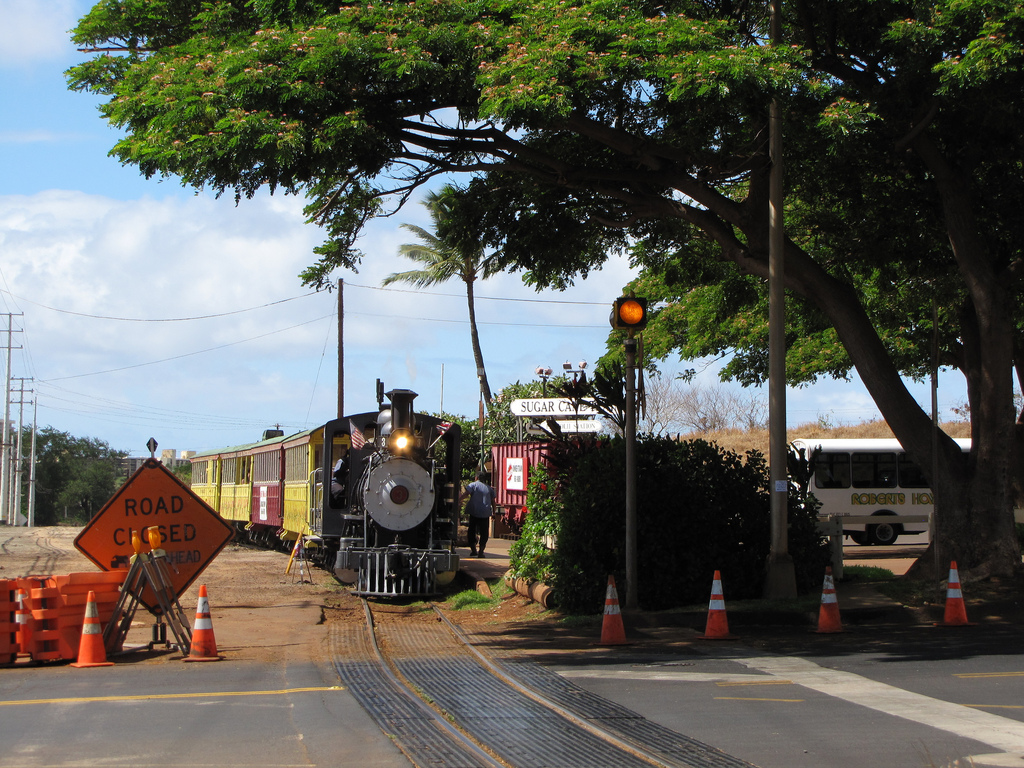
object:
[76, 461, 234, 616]
road sign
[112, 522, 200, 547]
closed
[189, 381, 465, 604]
train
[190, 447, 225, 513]
car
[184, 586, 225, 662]
street cone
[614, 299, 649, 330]
light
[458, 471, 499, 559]
person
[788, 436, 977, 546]
bus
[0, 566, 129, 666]
barricade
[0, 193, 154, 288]
clouds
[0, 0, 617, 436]
sky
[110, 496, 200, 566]
lettering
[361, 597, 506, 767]
tracks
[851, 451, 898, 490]
windows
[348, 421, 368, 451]
flags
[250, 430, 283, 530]
car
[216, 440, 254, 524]
cars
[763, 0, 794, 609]
pole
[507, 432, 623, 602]
bushes